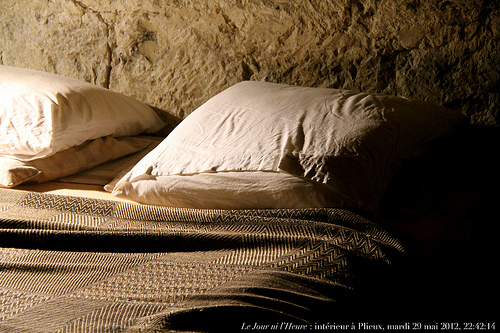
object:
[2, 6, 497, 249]
wall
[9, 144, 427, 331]
bed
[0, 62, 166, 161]
pillow case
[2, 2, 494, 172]
stone wall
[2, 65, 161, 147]
pillows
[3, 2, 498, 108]
wall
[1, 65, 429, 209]
pillows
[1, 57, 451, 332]
bed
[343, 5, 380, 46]
divot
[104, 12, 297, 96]
wall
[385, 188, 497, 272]
shadows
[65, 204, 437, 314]
quilt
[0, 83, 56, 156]
light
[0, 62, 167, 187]
pillow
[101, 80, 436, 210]
pillow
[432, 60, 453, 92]
divot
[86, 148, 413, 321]
divot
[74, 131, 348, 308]
bed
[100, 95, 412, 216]
pillow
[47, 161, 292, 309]
bed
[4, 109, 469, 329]
bed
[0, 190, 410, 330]
blanket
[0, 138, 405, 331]
blanket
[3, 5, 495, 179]
wall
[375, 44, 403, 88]
divot